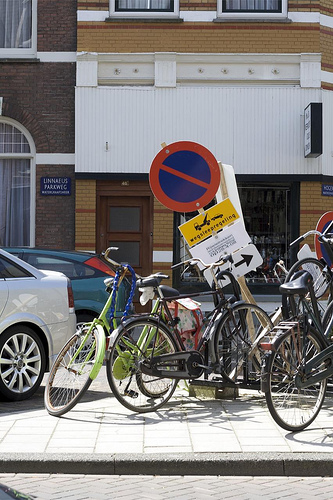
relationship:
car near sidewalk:
[0, 245, 77, 401] [0, 361, 330, 472]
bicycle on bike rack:
[43, 246, 179, 417] [203, 310, 331, 396]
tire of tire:
[106, 312, 182, 413] [106, 319, 180, 410]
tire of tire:
[263, 324, 328, 432] [263, 327, 327, 431]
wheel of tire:
[7, 330, 42, 384] [209, 298, 282, 394]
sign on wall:
[28, 161, 82, 220] [25, 53, 99, 213]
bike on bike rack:
[106, 269, 273, 413] [203, 310, 331, 396]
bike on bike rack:
[255, 220, 333, 433] [203, 310, 331, 396]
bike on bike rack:
[258, 255, 332, 429] [203, 310, 331, 396]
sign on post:
[145, 143, 226, 221] [213, 159, 272, 410]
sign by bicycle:
[145, 143, 226, 221] [43, 246, 179, 417]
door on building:
[96, 180, 152, 311] [66, 164, 330, 311]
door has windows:
[96, 180, 152, 311] [107, 206, 141, 270]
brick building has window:
[0, 1, 76, 277] [0, 114, 35, 247]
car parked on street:
[10, 225, 124, 415] [0, 295, 331, 380]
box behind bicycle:
[166, 295, 205, 359] [43, 246, 179, 417]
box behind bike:
[166, 295, 205, 359] [105, 252, 280, 415]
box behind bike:
[166, 295, 205, 359] [256, 228, 332, 430]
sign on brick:
[39, 175, 71, 196] [2, 0, 76, 256]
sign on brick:
[321, 183, 331, 198] [301, 179, 330, 299]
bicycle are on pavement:
[43, 246, 179, 417] [0, 356, 332, 466]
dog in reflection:
[244, 227, 311, 277] [182, 175, 298, 280]